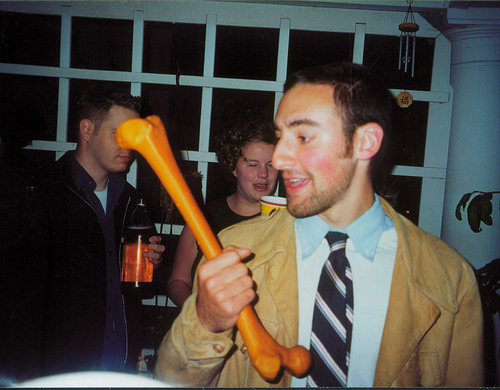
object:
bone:
[116, 115, 311, 383]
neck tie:
[308, 233, 354, 389]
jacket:
[154, 194, 482, 390]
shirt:
[288, 191, 401, 390]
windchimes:
[398, 0, 418, 77]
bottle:
[120, 204, 156, 299]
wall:
[0, 3, 500, 372]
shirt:
[64, 153, 127, 371]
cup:
[259, 196, 287, 216]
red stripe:
[260, 199, 288, 207]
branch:
[455, 190, 493, 232]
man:
[154, 61, 485, 387]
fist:
[197, 244, 256, 332]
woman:
[167, 106, 279, 308]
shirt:
[191, 196, 262, 284]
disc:
[399, 23, 420, 32]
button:
[214, 343, 224, 353]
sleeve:
[153, 292, 233, 384]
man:
[2, 89, 163, 386]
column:
[398, 3, 420, 77]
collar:
[293, 193, 385, 261]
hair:
[214, 119, 277, 181]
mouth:
[283, 175, 310, 191]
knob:
[118, 113, 154, 149]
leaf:
[455, 192, 471, 221]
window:
[361, 34, 435, 92]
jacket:
[5, 149, 142, 382]